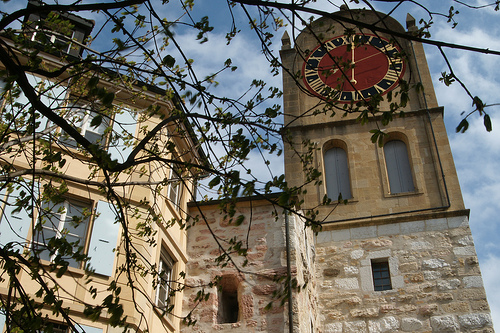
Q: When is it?
A: Daytime.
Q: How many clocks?
A: 1.